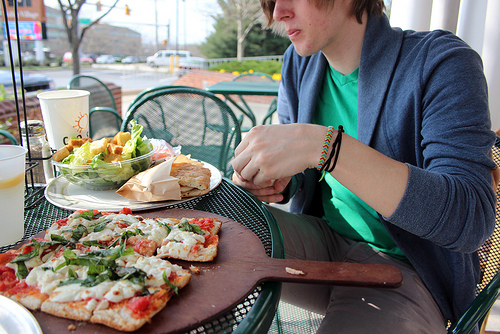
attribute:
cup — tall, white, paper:
[33, 86, 90, 158]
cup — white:
[19, 73, 111, 169]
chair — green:
[123, 91, 248, 183]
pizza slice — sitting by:
[138, 205, 252, 252]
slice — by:
[131, 260, 186, 307]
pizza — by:
[37, 215, 206, 302]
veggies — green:
[46, 234, 142, 280]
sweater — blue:
[264, 7, 499, 315]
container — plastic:
[54, 127, 160, 197]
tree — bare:
[57, 3, 99, 97]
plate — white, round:
[44, 154, 224, 211]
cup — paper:
[33, 87, 96, 142]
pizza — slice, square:
[2, 204, 223, 332]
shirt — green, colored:
[312, 55, 404, 252]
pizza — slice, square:
[0, 202, 235, 328]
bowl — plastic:
[49, 148, 171, 188]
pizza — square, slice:
[50, 250, 120, 302]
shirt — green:
[309, 59, 409, 264]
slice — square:
[92, 278, 167, 326]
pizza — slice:
[163, 209, 232, 267]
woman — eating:
[232, 0, 484, 302]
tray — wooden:
[26, 206, 406, 331]